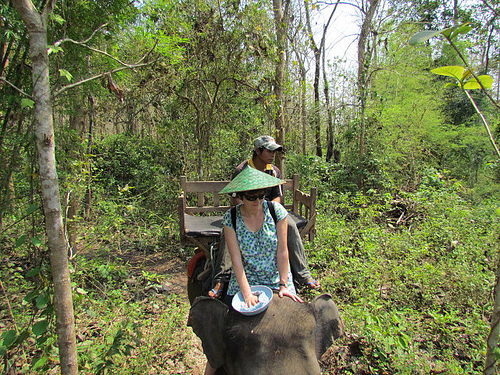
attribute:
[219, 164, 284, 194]
hat — green, small, blue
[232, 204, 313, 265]
shirt — blue, white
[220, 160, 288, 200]
hat — black, gray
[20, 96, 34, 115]
leaf — green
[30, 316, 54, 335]
leaf — green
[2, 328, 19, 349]
leaf — green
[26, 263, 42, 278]
leaf — green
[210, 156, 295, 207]
head — gray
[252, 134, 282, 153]
cap — green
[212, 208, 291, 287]
shirt — blue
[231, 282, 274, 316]
handle — blue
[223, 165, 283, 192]
woven hat — green, asian style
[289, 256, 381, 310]
slippers — blue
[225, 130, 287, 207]
man — sitting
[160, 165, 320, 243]
seat — wooden